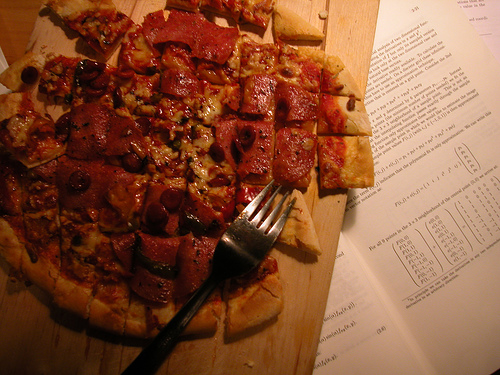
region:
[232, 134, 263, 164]
part of a food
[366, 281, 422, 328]
part of a paper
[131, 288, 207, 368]
part of a handke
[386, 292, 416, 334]
part of a paper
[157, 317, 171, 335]
part of a handle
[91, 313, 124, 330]
edge of a pizza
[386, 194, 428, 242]
part of a paper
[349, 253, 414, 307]
part of a partition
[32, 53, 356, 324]
round pizza on board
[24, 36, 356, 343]
board is light brown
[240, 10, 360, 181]
brown crust on pizza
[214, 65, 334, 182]
red pepperoni on pizza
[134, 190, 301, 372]
metal fork on pizza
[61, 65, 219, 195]
brown meat on pizza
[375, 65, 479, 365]
white paper under board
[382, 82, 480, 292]
black text on paper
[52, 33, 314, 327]
pizza sliced into squares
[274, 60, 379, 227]
small squares of pizza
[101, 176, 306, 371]
a fork is color silver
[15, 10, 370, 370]
a fork over a pizza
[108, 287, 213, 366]
handle of a silver fork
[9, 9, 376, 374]
a pizza over a cut board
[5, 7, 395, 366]
pizza is cut in small squares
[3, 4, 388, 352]
pizza has slices of pepperoni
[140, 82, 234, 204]
melted cheese on pizza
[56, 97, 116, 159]
slice of pepperoni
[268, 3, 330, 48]
a piece of crust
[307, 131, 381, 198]
a piece of crust with tomato sauce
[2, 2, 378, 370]
Food on a platter.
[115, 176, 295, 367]
Silver fork on a pizza.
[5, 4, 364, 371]
Pizza on a wooden tray.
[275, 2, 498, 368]
An open book.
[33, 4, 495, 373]
A wooden platter on top of an open book.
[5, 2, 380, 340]
Round pizza cut into small bites.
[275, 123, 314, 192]
A small bite of pizza.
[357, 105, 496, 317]
Words on a book.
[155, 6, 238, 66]
Two pieces of pepperoni.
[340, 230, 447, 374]
Crease in a book.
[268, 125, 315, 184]
peperoni on the pizza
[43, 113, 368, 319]
pepperoni cut into bite size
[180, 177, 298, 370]
fork on the pizza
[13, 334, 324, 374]
pizza on the wooden board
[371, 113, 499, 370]
paper with numbers next to meal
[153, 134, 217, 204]
melted cheese in the pizza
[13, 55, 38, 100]
black olives are in the mixture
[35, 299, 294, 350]
crust is cooked well done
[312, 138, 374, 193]
piece is hanging over edge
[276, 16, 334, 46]
corner peice has nothing on it